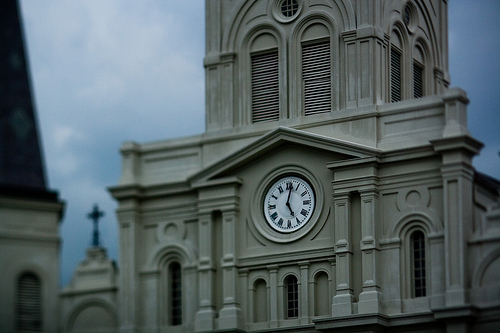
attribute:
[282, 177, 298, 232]
hands — Black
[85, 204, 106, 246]
cross — Blurry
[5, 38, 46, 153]
shapes — diamond shapes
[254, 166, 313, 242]
clock — black and white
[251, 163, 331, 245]
clock — round, black and white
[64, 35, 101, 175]
sky — blue, cloudy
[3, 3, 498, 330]
church — european, old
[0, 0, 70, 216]
steeple — black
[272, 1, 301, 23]
windows — Round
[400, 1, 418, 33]
windows — Round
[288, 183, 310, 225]
numbers — Roman numerals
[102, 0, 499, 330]
building — Tan , tall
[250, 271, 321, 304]
windows — dark, unlit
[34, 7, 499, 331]
building — fancy, Light 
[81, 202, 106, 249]
cross — Black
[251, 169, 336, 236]
clock — giant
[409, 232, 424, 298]
windows — Arched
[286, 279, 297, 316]
windows — Arched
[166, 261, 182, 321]
windows — Arched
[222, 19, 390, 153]
windows — arched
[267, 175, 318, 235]
clock — White 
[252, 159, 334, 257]
numbers — black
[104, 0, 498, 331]
clocktower — beige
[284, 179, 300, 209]
minutes — couple